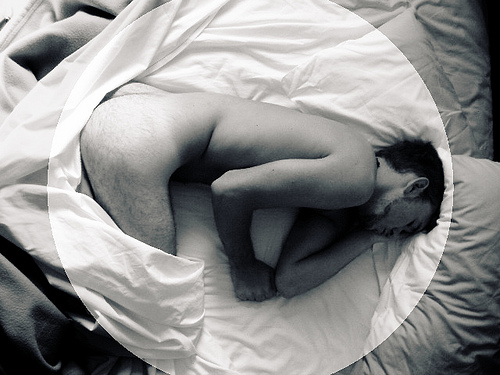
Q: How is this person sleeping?
A: In the nude.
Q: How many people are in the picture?
A: One.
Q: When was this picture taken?
A: Morning.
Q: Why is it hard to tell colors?
A: The picture is black and white.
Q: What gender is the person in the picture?
A: Male.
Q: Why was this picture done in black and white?
A: For artistic reasons.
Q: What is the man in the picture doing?
A: Sleeping.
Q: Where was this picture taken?
A: In a bedroom.